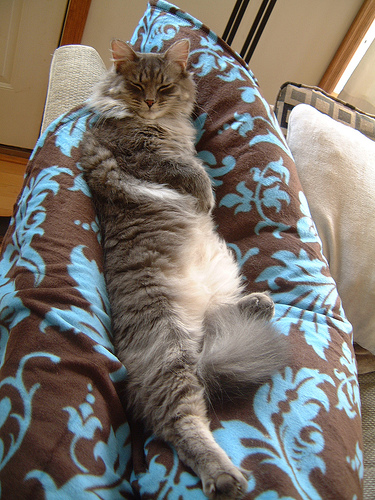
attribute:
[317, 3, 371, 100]
frame — wood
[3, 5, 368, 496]
blanket — blue, brown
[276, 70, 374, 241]
sofa — pattern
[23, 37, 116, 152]
couch — beige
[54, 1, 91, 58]
frame — brown door 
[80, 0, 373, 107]
wall — white 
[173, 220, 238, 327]
fur — White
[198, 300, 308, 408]
tail — cat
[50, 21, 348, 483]
cat — nose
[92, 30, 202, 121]
head — cat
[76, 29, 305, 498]
cat — gray, White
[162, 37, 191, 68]
ear — cat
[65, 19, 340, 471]
cat — paw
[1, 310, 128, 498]
blanket — brown, blue, patch